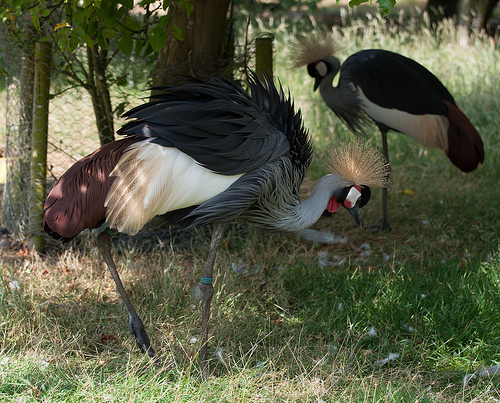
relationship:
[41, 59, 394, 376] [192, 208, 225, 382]
bird has right leg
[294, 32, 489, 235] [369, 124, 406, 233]
bird has legs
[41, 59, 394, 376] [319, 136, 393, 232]
bird has a head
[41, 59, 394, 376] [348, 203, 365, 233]
bird has a beak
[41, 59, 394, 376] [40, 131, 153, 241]
bird has a tail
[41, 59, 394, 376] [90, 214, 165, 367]
bird has left leg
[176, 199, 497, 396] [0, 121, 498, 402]
feathers on ground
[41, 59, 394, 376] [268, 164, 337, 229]
bird has a neck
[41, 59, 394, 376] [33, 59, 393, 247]
bird has feathers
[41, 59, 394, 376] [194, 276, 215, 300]
bird has right knee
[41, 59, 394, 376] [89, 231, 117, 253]
bird has left knee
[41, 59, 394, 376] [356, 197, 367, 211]
bird has right eye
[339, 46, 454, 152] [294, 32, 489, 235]
wing on bird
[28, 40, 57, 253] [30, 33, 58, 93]
stem has part